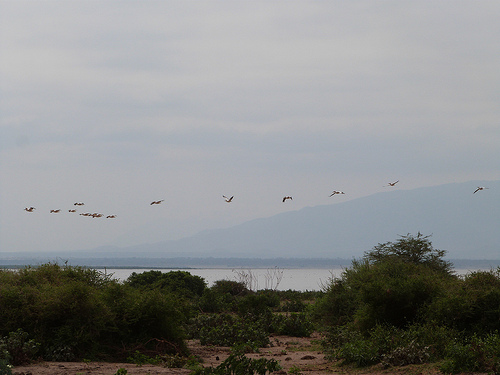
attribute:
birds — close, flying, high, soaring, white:
[116, 166, 385, 219]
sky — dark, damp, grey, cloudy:
[174, 28, 364, 133]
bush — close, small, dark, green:
[349, 245, 453, 321]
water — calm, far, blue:
[243, 263, 317, 299]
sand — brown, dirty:
[266, 335, 308, 364]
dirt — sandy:
[4, 328, 471, 373]